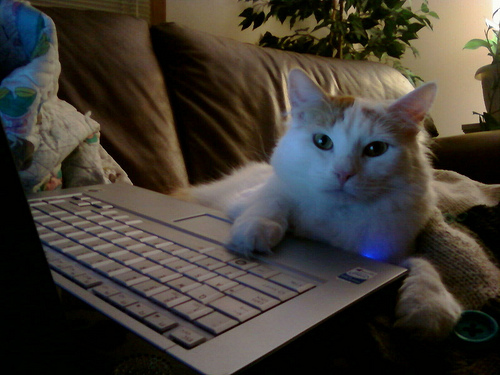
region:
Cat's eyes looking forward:
[309, 132, 392, 162]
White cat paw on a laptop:
[228, 205, 286, 253]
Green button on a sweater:
[451, 308, 498, 343]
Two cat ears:
[278, 63, 440, 125]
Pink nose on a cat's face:
[335, 170, 357, 182]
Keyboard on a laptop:
[15, 178, 410, 373]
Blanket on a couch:
[1, 0, 134, 195]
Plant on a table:
[468, 28, 498, 138]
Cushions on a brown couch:
[45, 8, 437, 197]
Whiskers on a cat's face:
[348, 176, 416, 195]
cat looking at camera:
[271, 61, 459, 268]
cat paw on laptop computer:
[209, 186, 284, 271]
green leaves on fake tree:
[268, 5, 404, 54]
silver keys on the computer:
[103, 233, 187, 319]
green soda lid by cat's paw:
[443, 276, 495, 347]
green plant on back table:
[478, 7, 498, 72]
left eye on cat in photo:
[296, 119, 348, 156]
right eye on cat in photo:
[360, 127, 410, 179]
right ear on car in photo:
[372, 67, 442, 128]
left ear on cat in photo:
[265, 47, 336, 99]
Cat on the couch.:
[177, 60, 482, 350]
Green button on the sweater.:
[452, 308, 493, 348]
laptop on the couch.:
[0, 115, 417, 373]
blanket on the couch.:
[0, 0, 141, 195]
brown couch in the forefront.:
[4, 3, 499, 370]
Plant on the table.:
[466, 7, 497, 121]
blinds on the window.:
[26, 0, 156, 23]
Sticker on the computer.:
[332, 258, 374, 288]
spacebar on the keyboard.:
[130, 215, 219, 256]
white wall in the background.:
[163, 1, 495, 140]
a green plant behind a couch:
[239, 0, 440, 70]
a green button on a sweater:
[453, 305, 498, 348]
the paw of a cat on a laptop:
[224, 213, 294, 256]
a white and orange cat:
[173, 68, 443, 256]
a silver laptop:
[0, 116, 410, 366]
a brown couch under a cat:
[40, 2, 496, 257]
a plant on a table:
[471, 8, 499, 129]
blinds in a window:
[26, 1, 155, 17]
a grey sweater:
[425, 211, 499, 298]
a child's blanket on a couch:
[0, 2, 143, 188]